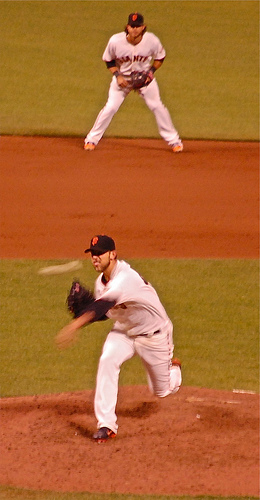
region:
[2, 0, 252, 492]
two baseball players on playing field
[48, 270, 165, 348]
pitcher's left hand blurred in motion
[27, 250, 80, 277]
baseball in mid-air appears blurry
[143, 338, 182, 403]
pitcher's left leg is bent behind him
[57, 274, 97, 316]
pitcher holding a black glove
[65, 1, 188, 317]
player behind pitcher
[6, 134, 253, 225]
player standing on reddish ground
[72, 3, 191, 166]
player standing with his legs wide apart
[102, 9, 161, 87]
player leaning forward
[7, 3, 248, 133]
smooth grass behind player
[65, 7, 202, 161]
player standing behind pitcher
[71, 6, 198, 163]
player with his legs spread apart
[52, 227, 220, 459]
pitcher throwing the ball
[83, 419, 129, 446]
right boot on the pitchers mound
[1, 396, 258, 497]
baseball pitchers mound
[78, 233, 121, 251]
hat on pitchers head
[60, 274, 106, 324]
pitchers glove in the right hand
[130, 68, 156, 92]
catchers mitt in the left hand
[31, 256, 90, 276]
blurred image of the ball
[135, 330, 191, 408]
left leg lifted off the ground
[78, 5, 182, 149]
A Giants player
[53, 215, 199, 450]
A Giants pitcher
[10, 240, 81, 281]
A baseball at high speed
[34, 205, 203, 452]
A pitcher throwing a baseball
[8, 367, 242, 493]
A baseball dirt mound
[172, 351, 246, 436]
The white pitcher's plate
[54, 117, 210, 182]
Orange baseball cleats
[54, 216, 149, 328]
A man with a beard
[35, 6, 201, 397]
Two baseball players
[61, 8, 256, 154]
A baseball player in the in field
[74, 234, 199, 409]
The man is pitching the ball.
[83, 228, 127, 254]
The baseball player has on a black cap.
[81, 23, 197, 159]
A baseball player ready to catch the ball.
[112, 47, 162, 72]
The word Giants written on the jersey.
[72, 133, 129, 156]
Man is wearing orange cleeks.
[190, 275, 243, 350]
The grass is green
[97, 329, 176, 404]
Man is wearing white pants.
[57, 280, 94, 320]
Baseball player has on a black glove.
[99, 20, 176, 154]
The player legs are spread.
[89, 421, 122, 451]
The player is wearing Nike sneakers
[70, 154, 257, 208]
the ground is brown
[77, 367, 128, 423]
the pants are white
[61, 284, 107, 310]
the glove is black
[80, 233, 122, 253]
the hat is black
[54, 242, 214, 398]
the guy just threw the ball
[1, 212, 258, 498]
the game is in a baseball park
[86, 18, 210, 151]
the man is waiting to catch the ball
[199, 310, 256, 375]
the lawn is green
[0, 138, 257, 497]
the photo was taken during the day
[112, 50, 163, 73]
he is playing for giants